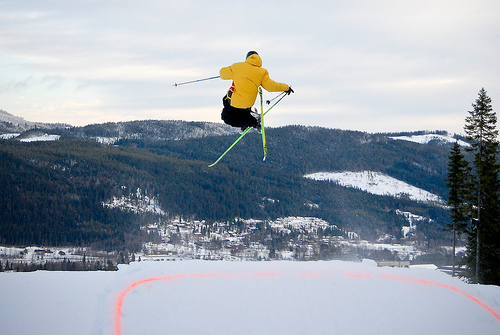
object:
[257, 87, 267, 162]
skis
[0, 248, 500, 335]
snow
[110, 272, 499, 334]
line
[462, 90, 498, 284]
pines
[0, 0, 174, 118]
sky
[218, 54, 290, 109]
jacket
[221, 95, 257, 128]
pants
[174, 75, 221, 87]
pole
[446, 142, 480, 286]
trees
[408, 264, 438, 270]
building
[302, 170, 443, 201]
clearing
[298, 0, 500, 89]
clouds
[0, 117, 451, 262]
forest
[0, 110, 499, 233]
mountain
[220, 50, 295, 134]
person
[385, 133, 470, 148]
snowcap